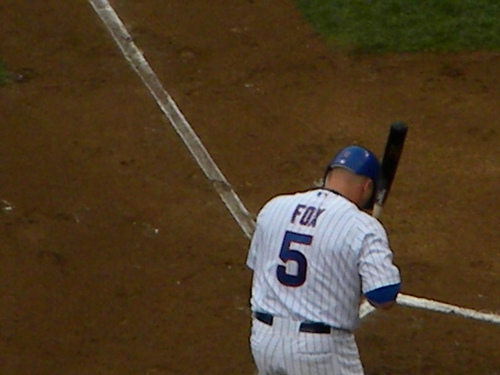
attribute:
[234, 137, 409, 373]
person — playing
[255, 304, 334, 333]
belt — black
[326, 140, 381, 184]
helmet — blue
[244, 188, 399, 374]
uniform — striped, white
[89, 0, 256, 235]
line — white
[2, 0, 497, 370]
dirt — brown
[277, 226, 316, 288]
5 — blue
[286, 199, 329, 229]
fox — blue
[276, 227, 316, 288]
number — blue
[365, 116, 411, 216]
bat — black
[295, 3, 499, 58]
grass patch — green, small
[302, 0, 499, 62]
grass patch — green, small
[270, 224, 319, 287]
number — 5